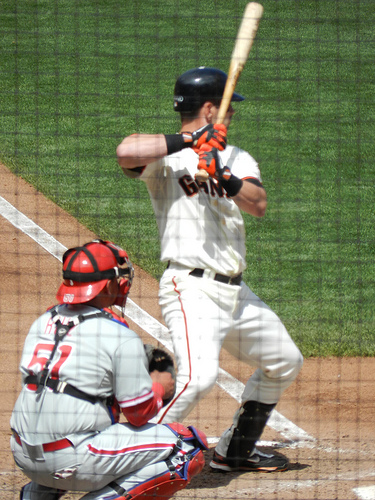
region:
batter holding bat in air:
[105, 9, 272, 224]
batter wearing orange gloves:
[154, 55, 284, 204]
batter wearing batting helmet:
[134, 35, 281, 159]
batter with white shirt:
[123, 79, 290, 328]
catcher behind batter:
[1, 224, 222, 445]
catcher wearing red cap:
[26, 230, 234, 474]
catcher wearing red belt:
[18, 227, 159, 474]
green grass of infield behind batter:
[102, 60, 302, 289]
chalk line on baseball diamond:
[15, 193, 177, 353]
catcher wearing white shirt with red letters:
[21, 229, 182, 469]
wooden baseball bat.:
[189, 3, 268, 192]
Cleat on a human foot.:
[204, 414, 300, 483]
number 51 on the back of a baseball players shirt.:
[18, 340, 81, 403]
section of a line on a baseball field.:
[270, 416, 319, 446]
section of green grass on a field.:
[293, 238, 346, 304]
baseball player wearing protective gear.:
[46, 214, 154, 344]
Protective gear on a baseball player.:
[149, 414, 224, 498]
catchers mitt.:
[134, 350, 180, 388]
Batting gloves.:
[169, 113, 237, 200]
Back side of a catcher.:
[19, 421, 87, 497]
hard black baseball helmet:
[168, 55, 253, 132]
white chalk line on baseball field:
[1, 203, 94, 299]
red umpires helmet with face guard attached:
[45, 235, 150, 318]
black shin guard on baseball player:
[230, 388, 286, 479]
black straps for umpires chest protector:
[25, 306, 161, 441]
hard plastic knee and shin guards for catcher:
[154, 415, 233, 499]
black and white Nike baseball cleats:
[206, 436, 295, 484]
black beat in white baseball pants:
[156, 236, 269, 302]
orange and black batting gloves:
[161, 120, 253, 194]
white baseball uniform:
[127, 132, 315, 429]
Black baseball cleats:
[203, 441, 306, 477]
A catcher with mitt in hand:
[8, 233, 193, 430]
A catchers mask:
[56, 232, 138, 307]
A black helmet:
[161, 60, 255, 120]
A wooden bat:
[184, 2, 269, 185]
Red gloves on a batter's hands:
[186, 113, 234, 182]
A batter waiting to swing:
[94, 55, 281, 259]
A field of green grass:
[271, 28, 364, 156]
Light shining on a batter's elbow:
[103, 128, 165, 167]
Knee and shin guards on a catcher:
[136, 415, 214, 490]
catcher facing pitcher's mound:
[10, 242, 209, 498]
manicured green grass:
[281, 113, 372, 316]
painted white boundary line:
[0, 190, 98, 271]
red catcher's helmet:
[50, 240, 130, 311]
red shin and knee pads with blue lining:
[117, 417, 209, 496]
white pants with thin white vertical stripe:
[157, 267, 206, 424]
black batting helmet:
[170, 64, 249, 122]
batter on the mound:
[108, 4, 327, 476]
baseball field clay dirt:
[311, 358, 372, 478]